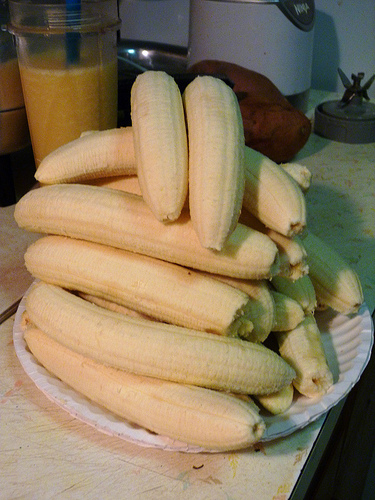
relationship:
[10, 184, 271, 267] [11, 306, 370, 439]
banana in a plate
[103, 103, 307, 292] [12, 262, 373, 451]
banana in a plate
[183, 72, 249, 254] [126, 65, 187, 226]
banana in a banana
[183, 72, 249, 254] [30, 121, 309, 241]
banana in a banana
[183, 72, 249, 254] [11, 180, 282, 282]
banana in a banana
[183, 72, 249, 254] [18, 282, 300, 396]
banana in a banana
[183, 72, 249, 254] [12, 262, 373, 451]
banana in a plate